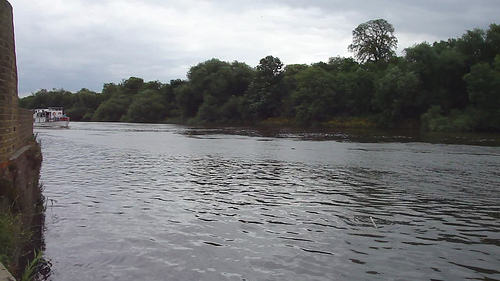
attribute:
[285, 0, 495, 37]
cloud — heavy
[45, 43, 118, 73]
cloud — moderate, layer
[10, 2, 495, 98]
cloudy — weather, in background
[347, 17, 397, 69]
green tree — tall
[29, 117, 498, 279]
water — river